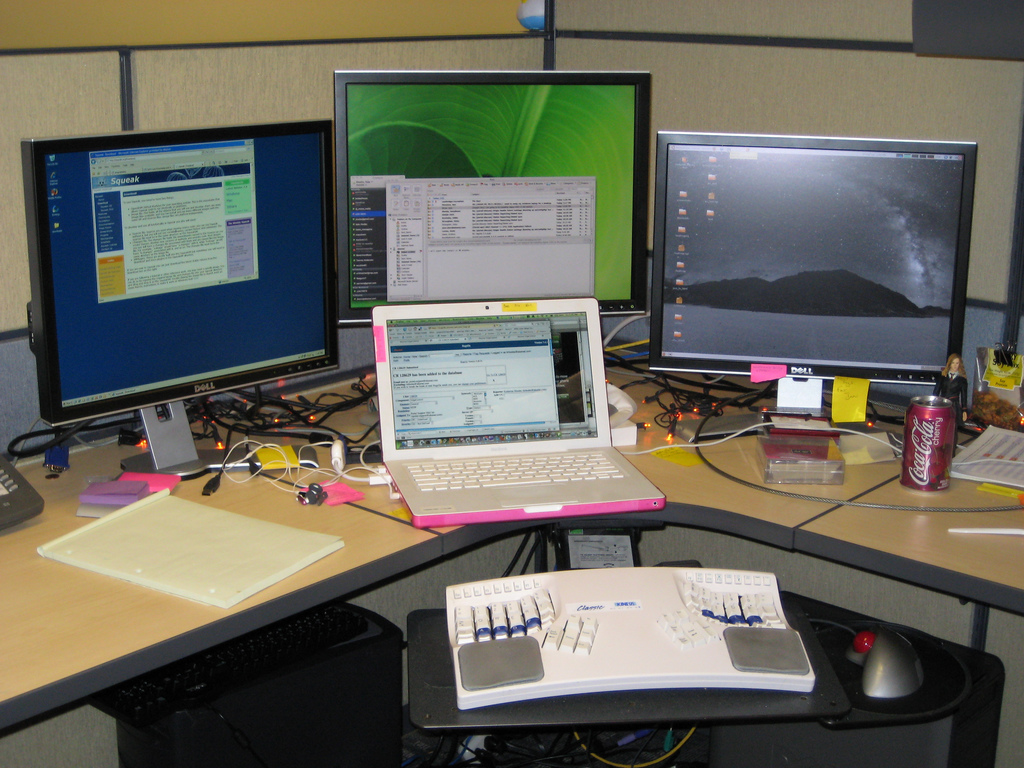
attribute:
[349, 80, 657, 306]
background — green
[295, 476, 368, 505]
pad — pink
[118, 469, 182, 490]
pad — pink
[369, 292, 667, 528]
laptop — white, pink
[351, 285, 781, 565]
laptop computer — white, pink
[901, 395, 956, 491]
can — red